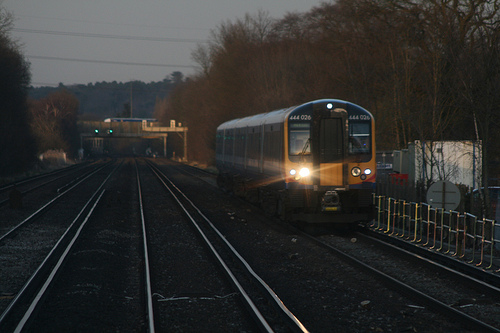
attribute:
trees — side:
[151, 1, 498, 228]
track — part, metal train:
[36, 186, 247, 306]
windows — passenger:
[213, 120, 284, 160]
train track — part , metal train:
[141, 281, 163, 330]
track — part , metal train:
[29, 156, 305, 331]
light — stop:
[105, 127, 115, 137]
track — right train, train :
[154, 153, 498, 332]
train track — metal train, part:
[239, 290, 275, 330]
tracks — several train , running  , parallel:
[190, 226, 390, 297]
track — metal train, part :
[4, 151, 495, 328]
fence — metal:
[374, 196, 496, 268]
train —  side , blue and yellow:
[207, 94, 378, 226]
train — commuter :
[196, 94, 403, 230]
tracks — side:
[6, 152, 497, 332]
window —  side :
[217, 132, 282, 157]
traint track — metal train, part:
[107, 245, 310, 315]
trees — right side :
[236, 28, 498, 126]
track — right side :
[58, 127, 405, 302]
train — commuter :
[205, 102, 365, 227]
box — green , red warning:
[406, 140, 483, 189]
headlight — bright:
[281, 160, 319, 187]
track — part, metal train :
[152, 156, 311, 331]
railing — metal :
[378, 194, 485, 258]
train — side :
[210, 99, 378, 238]